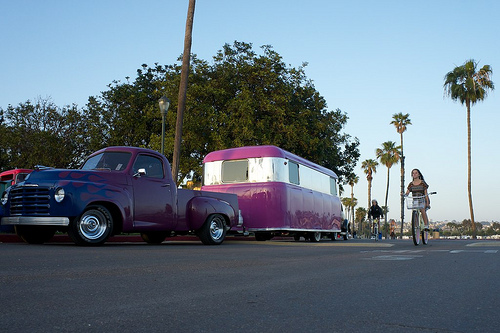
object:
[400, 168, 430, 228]
woman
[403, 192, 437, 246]
bicycle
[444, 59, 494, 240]
palm tree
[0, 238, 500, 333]
street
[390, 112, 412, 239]
palm tree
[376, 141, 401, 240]
palm tree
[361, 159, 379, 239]
palm tree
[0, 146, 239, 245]
truck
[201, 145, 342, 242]
purple trailer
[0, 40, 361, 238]
trees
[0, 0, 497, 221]
sky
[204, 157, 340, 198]
section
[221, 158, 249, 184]
window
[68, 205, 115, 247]
rim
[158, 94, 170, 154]
lamo post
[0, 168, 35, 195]
truck cab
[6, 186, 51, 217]
grill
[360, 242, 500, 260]
white lines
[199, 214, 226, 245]
tire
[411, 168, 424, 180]
dark hair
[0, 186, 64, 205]
headlights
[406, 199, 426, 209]
basket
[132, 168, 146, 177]
mirror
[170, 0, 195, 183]
pole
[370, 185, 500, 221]
clouds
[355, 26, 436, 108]
clouds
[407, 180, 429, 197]
brown shirt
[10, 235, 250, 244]
curb